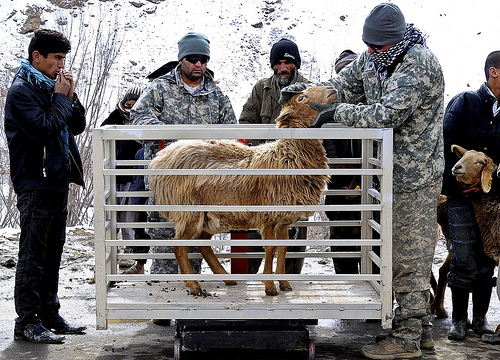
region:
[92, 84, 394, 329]
a goat in a small metal pen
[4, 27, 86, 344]
man with light blue scarf standing to left of the goat in the pen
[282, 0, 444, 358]
man in cammo uniform holding goat's head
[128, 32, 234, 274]
man in cammo uniform, sunglasses, and hat to left of man touching goat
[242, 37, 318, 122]
man with beard and dark knit hat behind goat's head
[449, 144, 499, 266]
goat to far right of the penned goat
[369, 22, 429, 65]
scarf man touching the goat is wearing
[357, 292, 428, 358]
foreground boot worn by man touching the goat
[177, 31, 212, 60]
hat worn by man in cammo left of the man touching the goat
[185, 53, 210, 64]
sunglasses of man in cammo who is left of the bearded man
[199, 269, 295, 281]
metal strip on cage.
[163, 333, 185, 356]
wheel under the cage.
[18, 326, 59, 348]
black shoe on man's foot.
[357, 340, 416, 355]
tennis shoe on man's foot.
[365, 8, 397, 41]
stocking cap on man's head.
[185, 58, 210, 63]
sunglasses on man's face.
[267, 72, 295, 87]
beard on man's face.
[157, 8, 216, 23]
snow on the hill.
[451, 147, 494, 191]
head of the sheep.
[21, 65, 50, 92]
scarf around man's neck.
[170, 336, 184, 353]
wheel of the cart.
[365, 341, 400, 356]
shoe on man's foot.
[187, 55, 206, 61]
sunglasses on man's face.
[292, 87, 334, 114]
face of the sheep.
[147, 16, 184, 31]
snow on the hill.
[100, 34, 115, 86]
bare branch of bush.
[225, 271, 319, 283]
metal strip on cage.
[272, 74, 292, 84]
beard on man's face.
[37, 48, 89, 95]
the man is trying to warm his hands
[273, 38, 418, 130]
the man is checking out the sheep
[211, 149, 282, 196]
the sheep is brown in color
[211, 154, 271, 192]
the sheep has a lot of hair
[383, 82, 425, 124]
the jacket is camo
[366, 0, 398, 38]
the hat is gray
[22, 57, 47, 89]
the scarf is blue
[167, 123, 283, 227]
the cage is white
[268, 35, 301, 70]
the hat is black and white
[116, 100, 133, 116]
the scarf is brown white and black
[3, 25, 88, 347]
a guy wearing cowboy boots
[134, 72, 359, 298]
a brown sheep being considered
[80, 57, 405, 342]
a sheep in a cage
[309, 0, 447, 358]
a guy wearing camo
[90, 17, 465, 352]
a guy inspecting a sheep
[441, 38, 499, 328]
a guy holding another sheep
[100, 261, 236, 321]
a lot of goat droppings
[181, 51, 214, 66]
a pair of black sunglasses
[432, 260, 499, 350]
black rubber boots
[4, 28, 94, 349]
a guy warming his hands